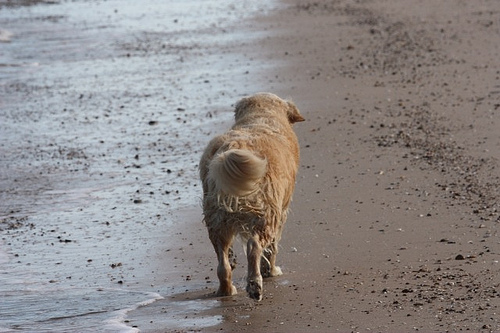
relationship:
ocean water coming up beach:
[0, 5, 226, 331] [226, 5, 493, 329]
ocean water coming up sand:
[0, 5, 226, 331] [226, 9, 444, 329]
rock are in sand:
[455, 254, 464, 260] [289, 16, 497, 330]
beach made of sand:
[16, 15, 487, 326] [276, 19, 471, 281]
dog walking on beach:
[197, 92, 305, 302] [16, 15, 487, 326]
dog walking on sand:
[193, 92, 303, 302] [134, 207, 485, 327]